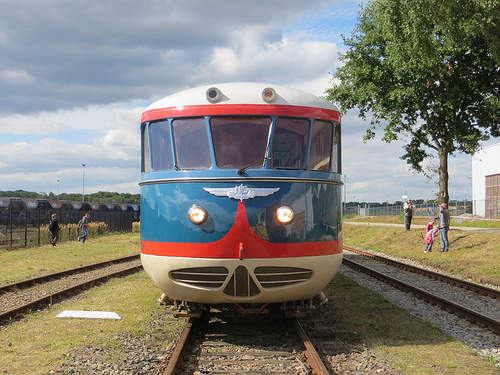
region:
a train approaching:
[115, 65, 384, 368]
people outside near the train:
[313, 110, 488, 262]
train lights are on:
[138, 76, 350, 290]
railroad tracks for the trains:
[50, 179, 460, 374]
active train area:
[27, 155, 403, 361]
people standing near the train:
[35, 163, 185, 335]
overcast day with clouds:
[78, 27, 370, 237]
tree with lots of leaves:
[325, 12, 499, 254]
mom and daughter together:
[358, 152, 498, 303]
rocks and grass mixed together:
[82, 241, 242, 373]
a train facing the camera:
[129, 60, 391, 330]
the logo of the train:
[163, 165, 328, 206]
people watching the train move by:
[393, 193, 470, 280]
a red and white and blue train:
[102, 63, 397, 320]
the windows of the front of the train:
[98, 101, 392, 165]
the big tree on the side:
[327, 2, 497, 239]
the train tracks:
[40, 314, 405, 373]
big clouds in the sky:
[50, 34, 266, 79]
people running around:
[46, 206, 118, 259]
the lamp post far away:
[54, 151, 108, 198]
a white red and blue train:
[133, 72, 364, 326]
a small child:
[423, 217, 440, 252]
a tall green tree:
[345, 0, 499, 255]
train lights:
[135, 178, 350, 244]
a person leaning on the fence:
[47, 202, 69, 253]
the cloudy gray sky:
[18, 0, 121, 179]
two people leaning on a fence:
[12, 185, 129, 260]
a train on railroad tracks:
[130, 72, 359, 373]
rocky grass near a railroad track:
[73, 323, 427, 373]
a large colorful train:
[124, 73, 377, 335]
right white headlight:
[274, 204, 294, 225]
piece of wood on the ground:
[55, 303, 120, 323]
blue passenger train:
[123, 73, 363, 319]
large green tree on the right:
[325, 5, 495, 240]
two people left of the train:
[40, 205, 105, 245]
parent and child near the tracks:
[415, 196, 455, 252]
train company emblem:
[195, 181, 280, 196]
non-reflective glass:
[135, 120, 340, 175]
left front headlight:
[186, 205, 201, 220]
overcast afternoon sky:
[3, 0, 298, 130]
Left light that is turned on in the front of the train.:
[184, 207, 209, 224]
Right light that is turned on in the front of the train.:
[269, 203, 296, 230]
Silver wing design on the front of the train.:
[201, 180, 286, 203]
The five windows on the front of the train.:
[142, 110, 339, 172]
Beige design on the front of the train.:
[140, 255, 339, 300]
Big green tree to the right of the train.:
[335, 3, 499, 245]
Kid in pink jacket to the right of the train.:
[416, 219, 438, 254]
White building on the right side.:
[468, 147, 499, 222]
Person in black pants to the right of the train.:
[394, 192, 419, 231]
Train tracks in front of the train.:
[175, 310, 324, 374]